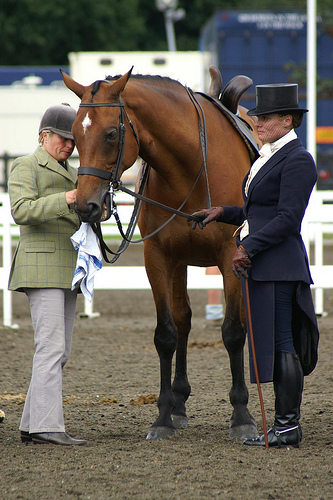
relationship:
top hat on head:
[246, 83, 309, 116] [251, 112, 303, 138]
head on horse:
[56, 67, 140, 222] [62, 71, 270, 449]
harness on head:
[75, 80, 214, 262] [56, 67, 140, 222]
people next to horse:
[7, 85, 318, 447] [62, 71, 270, 449]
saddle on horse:
[221, 70, 263, 148] [62, 71, 270, 449]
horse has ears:
[62, 71, 270, 449] [59, 67, 133, 95]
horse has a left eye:
[62, 71, 270, 449] [106, 127, 119, 142]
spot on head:
[81, 112, 92, 135] [56, 67, 140, 222]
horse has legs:
[62, 71, 270, 449] [144, 239, 257, 443]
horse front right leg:
[62, 71, 270, 449] [144, 246, 179, 444]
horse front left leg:
[62, 71, 270, 449] [223, 239, 262, 441]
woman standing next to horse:
[192, 82, 320, 444] [62, 71, 270, 449]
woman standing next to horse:
[4, 102, 85, 446] [62, 71, 270, 449]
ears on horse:
[59, 67, 133, 95] [62, 71, 270, 449]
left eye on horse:
[106, 127, 119, 142] [62, 71, 270, 449]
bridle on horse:
[75, 80, 214, 262] [62, 71, 270, 449]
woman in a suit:
[192, 82, 320, 444] [221, 129, 321, 382]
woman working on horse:
[4, 102, 85, 446] [62, 71, 270, 449]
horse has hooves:
[62, 71, 270, 449] [146, 413, 263, 441]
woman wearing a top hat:
[192, 82, 320, 444] [246, 83, 309, 116]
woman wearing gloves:
[192, 82, 320, 444] [190, 206, 252, 281]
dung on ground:
[102, 393, 156, 408] [0, 237, 331, 498]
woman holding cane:
[192, 82, 320, 444] [243, 266, 271, 446]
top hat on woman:
[246, 83, 309, 116] [192, 82, 320, 444]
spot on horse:
[81, 112, 92, 135] [62, 71, 270, 449]